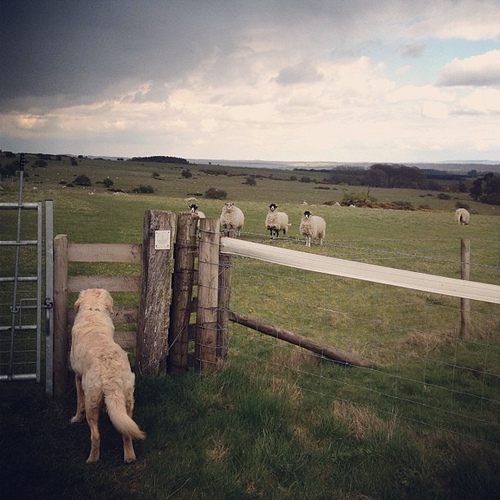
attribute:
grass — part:
[296, 418, 376, 462]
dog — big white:
[71, 280, 148, 450]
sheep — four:
[297, 208, 331, 250]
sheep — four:
[259, 199, 293, 238]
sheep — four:
[222, 194, 242, 233]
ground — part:
[198, 376, 416, 457]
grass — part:
[279, 425, 317, 452]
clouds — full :
[0, 2, 498, 164]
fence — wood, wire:
[57, 216, 495, 420]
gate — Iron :
[4, 177, 185, 367]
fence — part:
[8, 187, 498, 438]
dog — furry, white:
[40, 274, 185, 499]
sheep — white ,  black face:
[290, 184, 330, 258]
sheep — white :
[294, 212, 328, 243]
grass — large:
[19, 186, 222, 260]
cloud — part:
[264, 43, 324, 93]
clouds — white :
[217, 58, 434, 158]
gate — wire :
[218, 221, 493, 461]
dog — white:
[67, 286, 143, 464]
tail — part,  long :
[102, 380, 149, 442]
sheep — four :
[217, 183, 475, 248]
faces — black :
[265, 196, 318, 225]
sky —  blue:
[26, 11, 481, 172]